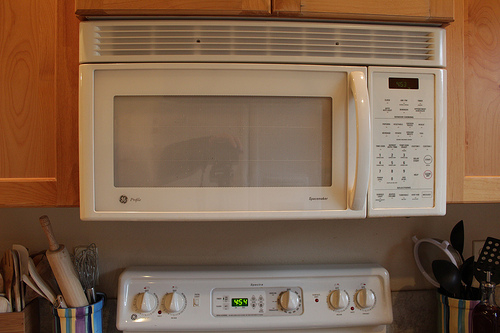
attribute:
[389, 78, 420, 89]
clock — digital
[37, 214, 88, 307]
rolling pin — wooden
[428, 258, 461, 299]
item — cooking untensil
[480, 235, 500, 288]
item — cooking untensil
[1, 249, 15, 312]
item — cooking untensil, wooden, fork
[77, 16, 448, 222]
microwave — built in, white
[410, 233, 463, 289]
strainer — metal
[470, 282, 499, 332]
bottle — brown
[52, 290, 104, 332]
container — striped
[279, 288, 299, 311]
knob — white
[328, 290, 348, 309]
knob — white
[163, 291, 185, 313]
knob — white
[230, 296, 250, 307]
clock — digital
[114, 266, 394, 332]
oven — white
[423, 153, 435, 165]
botton — digital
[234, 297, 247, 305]
4:54 — green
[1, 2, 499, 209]
cabinets — light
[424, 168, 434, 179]
botton — digital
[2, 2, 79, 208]
cabinet door — brown